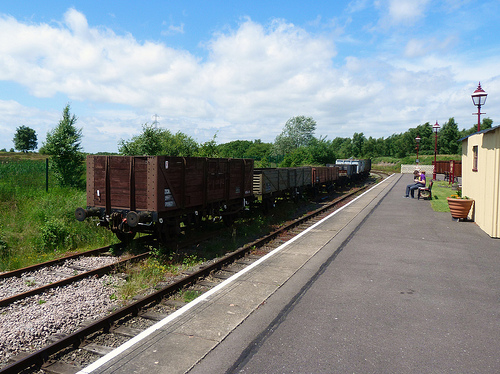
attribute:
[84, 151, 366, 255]
train — gray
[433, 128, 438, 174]
pole — red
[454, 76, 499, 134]
lamp — off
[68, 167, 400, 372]
white edge — concrete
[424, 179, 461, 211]
grass — green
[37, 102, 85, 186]
tree — green 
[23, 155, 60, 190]
post — black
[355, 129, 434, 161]
trees — green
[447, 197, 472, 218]
jar — brown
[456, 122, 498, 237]
wall — yellow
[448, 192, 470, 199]
flowers — orange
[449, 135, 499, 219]
building — yellow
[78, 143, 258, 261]
wagon — brown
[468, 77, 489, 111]
light — red